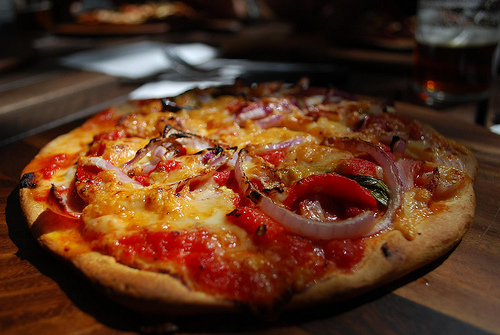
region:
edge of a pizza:
[355, 270, 395, 310]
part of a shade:
[435, 299, 457, 334]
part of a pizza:
[249, 238, 313, 322]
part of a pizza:
[448, 216, 468, 247]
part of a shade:
[411, 288, 432, 330]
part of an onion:
[295, 189, 332, 250]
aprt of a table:
[426, 288, 452, 331]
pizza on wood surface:
[4, 72, 493, 333]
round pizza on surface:
[17, 81, 473, 316]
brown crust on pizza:
[89, 263, 187, 308]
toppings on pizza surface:
[59, 101, 429, 292]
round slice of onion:
[236, 136, 393, 237]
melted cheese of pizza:
[108, 187, 243, 229]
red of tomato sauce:
[147, 232, 249, 282]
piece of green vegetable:
[353, 172, 392, 207]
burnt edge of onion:
[138, 123, 175, 152]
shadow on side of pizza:
[4, 189, 161, 334]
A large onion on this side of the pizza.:
[236, 134, 400, 239]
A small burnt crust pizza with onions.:
[19, 80, 474, 310]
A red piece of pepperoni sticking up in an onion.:
[279, 170, 380, 209]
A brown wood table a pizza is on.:
[0, 96, 499, 332]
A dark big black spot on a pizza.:
[16, 171, 36, 189]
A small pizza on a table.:
[20, 80, 478, 309]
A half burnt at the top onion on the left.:
[86, 125, 224, 187]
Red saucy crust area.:
[131, 206, 366, 301]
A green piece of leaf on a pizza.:
[338, 173, 391, 208]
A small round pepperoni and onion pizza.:
[18, 84, 475, 309]